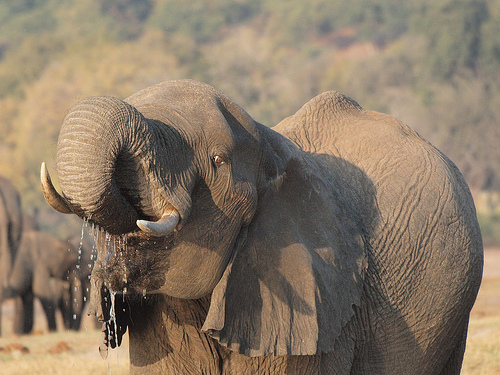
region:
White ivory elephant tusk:
[129, 207, 189, 244]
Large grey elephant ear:
[202, 165, 369, 373]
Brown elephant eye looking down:
[208, 144, 233, 175]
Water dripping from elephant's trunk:
[71, 211, 153, 351]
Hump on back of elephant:
[309, 82, 377, 139]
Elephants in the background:
[0, 223, 95, 345]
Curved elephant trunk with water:
[54, 93, 139, 234]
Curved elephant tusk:
[31, 156, 81, 229]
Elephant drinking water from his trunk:
[39, 76, 342, 338]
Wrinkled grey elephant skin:
[341, 139, 462, 353]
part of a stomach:
[401, 230, 437, 332]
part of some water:
[89, 284, 128, 329]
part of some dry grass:
[71, 352, 96, 370]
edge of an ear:
[296, 341, 333, 364]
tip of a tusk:
[130, 210, 155, 237]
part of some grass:
[476, 311, 496, 358]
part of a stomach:
[416, 253, 451, 319]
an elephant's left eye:
[206, 144, 228, 169]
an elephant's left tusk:
[135, 205, 182, 240]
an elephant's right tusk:
[40, 158, 69, 212]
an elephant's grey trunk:
[55, 94, 190, 233]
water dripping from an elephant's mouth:
[72, 217, 127, 354]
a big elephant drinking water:
[38, 78, 485, 374]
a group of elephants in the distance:
[0, 178, 91, 336]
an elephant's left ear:
[200, 164, 367, 356]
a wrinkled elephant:
[42, 78, 489, 374]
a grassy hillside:
[0, 4, 495, 243]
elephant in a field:
[35, 49, 487, 374]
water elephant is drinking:
[63, 218, 160, 342]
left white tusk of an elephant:
[129, 196, 186, 241]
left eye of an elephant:
[203, 145, 235, 173]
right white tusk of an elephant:
[26, 156, 83, 225]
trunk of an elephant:
[52, 82, 152, 249]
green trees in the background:
[7, 4, 494, 80]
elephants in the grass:
[2, 163, 95, 350]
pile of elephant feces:
[47, 335, 78, 365]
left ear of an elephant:
[204, 216, 383, 359]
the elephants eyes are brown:
[200, 147, 232, 172]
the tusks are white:
[124, 200, 185, 234]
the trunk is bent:
[12, 89, 190, 295]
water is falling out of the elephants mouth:
[45, 207, 178, 312]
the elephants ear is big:
[189, 137, 364, 372]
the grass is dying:
[8, 326, 123, 368]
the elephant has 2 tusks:
[6, 157, 196, 261]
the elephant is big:
[29, 65, 497, 315]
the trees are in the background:
[202, 0, 497, 120]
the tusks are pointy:
[86, 190, 193, 260]